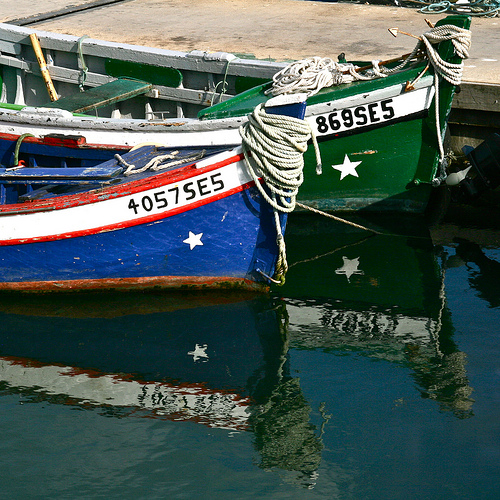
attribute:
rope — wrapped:
[238, 60, 314, 222]